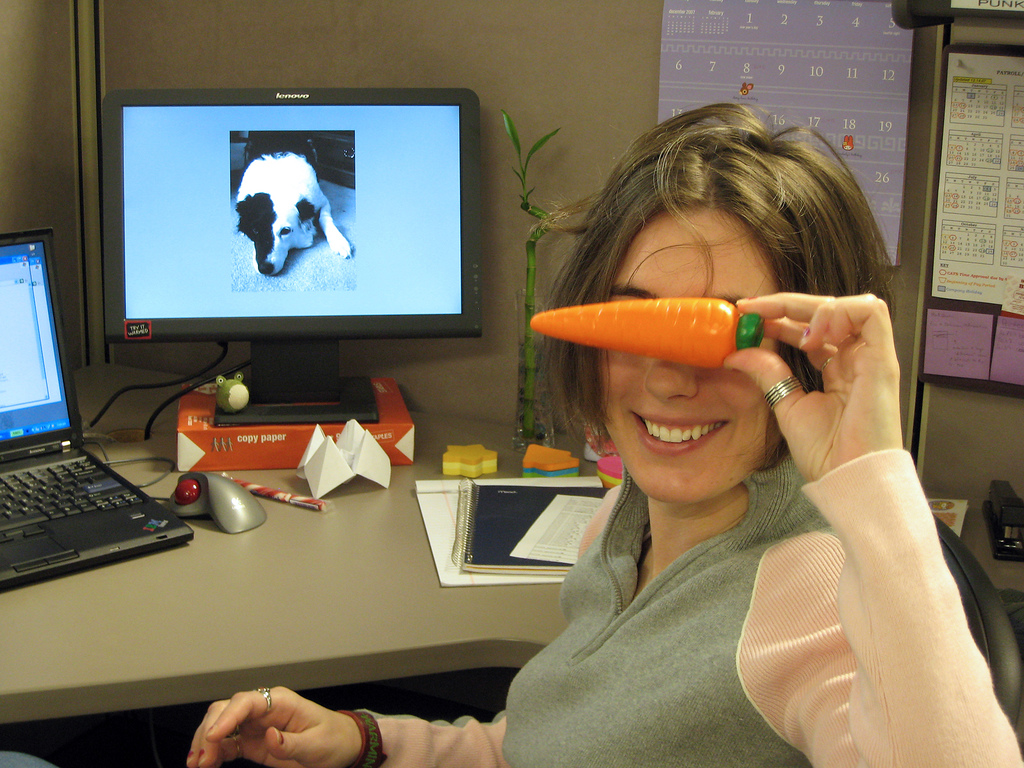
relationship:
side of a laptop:
[9, 227, 200, 595] [1, 227, 200, 595]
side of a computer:
[9, 227, 200, 595] [3, 230, 192, 602]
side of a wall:
[880, 5, 1019, 502] [897, 7, 1019, 608]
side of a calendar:
[880, 5, 1019, 502] [925, 48, 1019, 321]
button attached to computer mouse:
[150, 452, 207, 498] [170, 471, 268, 534]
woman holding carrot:
[505, 68, 918, 641] [505, 270, 821, 364]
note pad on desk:
[442, 444, 497, 478] [7, 406, 1008, 765]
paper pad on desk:
[519, 434, 582, 482] [9, 372, 1021, 736]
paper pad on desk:
[590, 440, 634, 495] [7, 406, 1008, 765]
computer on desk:
[0, 227, 192, 589] [7, 406, 1008, 765]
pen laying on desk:
[229, 470, 325, 514] [9, 372, 1021, 736]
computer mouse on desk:
[170, 471, 268, 534] [2, 432, 1018, 744]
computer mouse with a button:
[173, 458, 269, 551] [175, 478, 201, 505]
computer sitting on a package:
[102, 87, 484, 428] [158, 369, 429, 491]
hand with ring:
[720, 276, 909, 480] [758, 365, 802, 413]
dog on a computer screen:
[222, 146, 348, 283] [110, 82, 486, 353]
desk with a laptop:
[9, 372, 1021, 736] [6, 250, 188, 607]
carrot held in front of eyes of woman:
[512, 280, 761, 373] [117, 82, 1014, 763]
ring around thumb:
[765, 363, 809, 415] [726, 324, 832, 422]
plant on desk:
[454, 93, 584, 467] [28, 332, 750, 719]